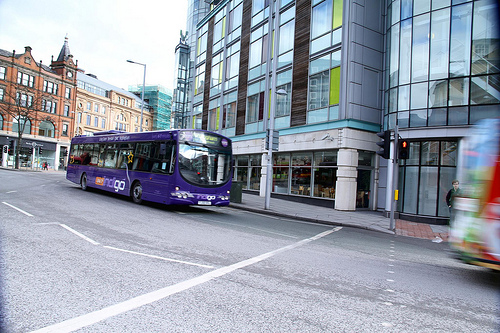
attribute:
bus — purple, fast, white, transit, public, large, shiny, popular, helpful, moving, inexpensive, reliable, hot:
[59, 126, 238, 212]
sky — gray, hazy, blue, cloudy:
[26, 1, 49, 16]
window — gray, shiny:
[204, 55, 223, 79]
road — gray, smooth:
[108, 217, 146, 237]